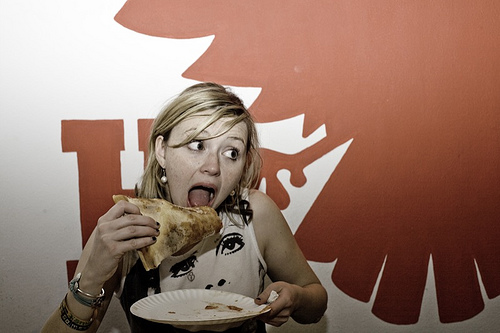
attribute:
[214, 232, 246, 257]
eye — black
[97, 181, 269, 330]
shirt — white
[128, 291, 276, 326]
plate — paper plate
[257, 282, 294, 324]
hand — woman's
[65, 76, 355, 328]
woman — Eating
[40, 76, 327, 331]
lady — young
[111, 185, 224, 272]
pizza — sliced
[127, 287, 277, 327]
plate — white,  paper, paper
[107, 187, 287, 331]
shirt — black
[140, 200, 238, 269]
shirt — white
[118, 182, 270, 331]
shirt — white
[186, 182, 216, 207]
mouth — Open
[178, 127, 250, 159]
eyes — brown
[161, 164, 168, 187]
earring — woman's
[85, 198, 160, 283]
hand — right hand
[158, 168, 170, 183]
earring — White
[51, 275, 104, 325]
bracelets — colorful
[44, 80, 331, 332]
woman — wearing, blonde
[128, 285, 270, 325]
paper plate — White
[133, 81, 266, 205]
hair — long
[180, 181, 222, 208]
mouth — woman's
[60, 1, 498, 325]
symbol — red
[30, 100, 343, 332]
woman — Eating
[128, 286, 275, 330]
paper plate — white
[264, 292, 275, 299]
napkin —  white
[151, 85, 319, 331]
woman — caucasian, eating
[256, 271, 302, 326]
hand — holding pizza, holding a plate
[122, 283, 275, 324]
paper plate — white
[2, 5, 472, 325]
wall — red, white